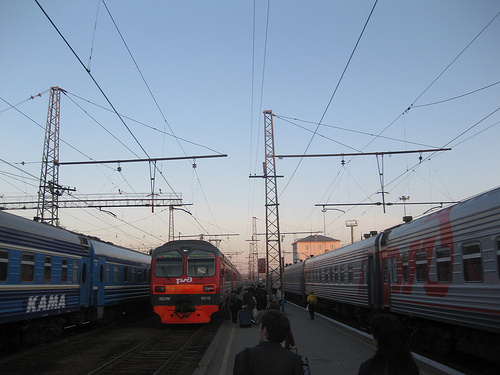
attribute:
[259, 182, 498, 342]
train — gray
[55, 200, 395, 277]
clouds — white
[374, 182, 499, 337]
passenger car — silver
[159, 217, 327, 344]
rail — red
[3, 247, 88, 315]
compartment — blue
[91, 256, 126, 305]
compartment — blue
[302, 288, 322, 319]
passenger — potential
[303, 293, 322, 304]
shirt — yellow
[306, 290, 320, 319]
person — wearing, yellow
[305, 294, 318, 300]
shirt — t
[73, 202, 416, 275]
clouds — white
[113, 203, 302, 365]
train — boarding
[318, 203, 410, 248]
cloud — white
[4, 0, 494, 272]
sky — blue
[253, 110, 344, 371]
rail — electric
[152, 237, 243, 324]
train — red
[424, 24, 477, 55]
sky — blue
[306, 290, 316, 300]
t shirt — yellow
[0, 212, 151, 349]
train — blue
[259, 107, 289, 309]
electric pole — standing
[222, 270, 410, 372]
people — some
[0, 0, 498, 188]
sky — blue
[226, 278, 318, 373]
people — standing, walking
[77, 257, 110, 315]
doors — entry, exit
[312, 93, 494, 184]
clouds — white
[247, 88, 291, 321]
tower — metal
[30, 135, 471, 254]
clouds — white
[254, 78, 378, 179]
clouds — white